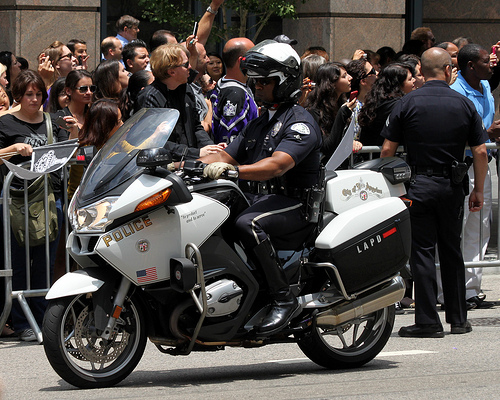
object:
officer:
[145, 39, 325, 335]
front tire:
[40, 281, 152, 381]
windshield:
[102, 103, 180, 164]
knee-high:
[244, 238, 289, 293]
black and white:
[240, 41, 301, 111]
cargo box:
[327, 170, 405, 214]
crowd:
[5, 15, 499, 146]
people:
[6, 70, 70, 148]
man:
[133, 43, 223, 160]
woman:
[353, 64, 415, 145]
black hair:
[355, 62, 411, 145]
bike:
[46, 102, 414, 389]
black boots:
[245, 236, 305, 335]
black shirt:
[386, 81, 484, 168]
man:
[448, 46, 497, 308]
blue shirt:
[449, 71, 496, 142]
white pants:
[440, 166, 492, 300]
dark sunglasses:
[247, 79, 278, 91]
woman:
[57, 73, 95, 139]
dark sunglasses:
[77, 86, 98, 94]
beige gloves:
[204, 161, 235, 181]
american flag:
[135, 266, 158, 284]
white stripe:
[253, 199, 304, 243]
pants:
[241, 188, 312, 266]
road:
[95, 100, 445, 399]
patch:
[288, 122, 313, 134]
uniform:
[235, 102, 325, 335]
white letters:
[359, 246, 365, 253]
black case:
[316, 195, 413, 298]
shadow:
[114, 360, 294, 387]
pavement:
[10, 362, 55, 388]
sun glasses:
[367, 66, 381, 78]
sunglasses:
[164, 57, 196, 69]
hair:
[148, 43, 185, 82]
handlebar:
[180, 159, 239, 179]